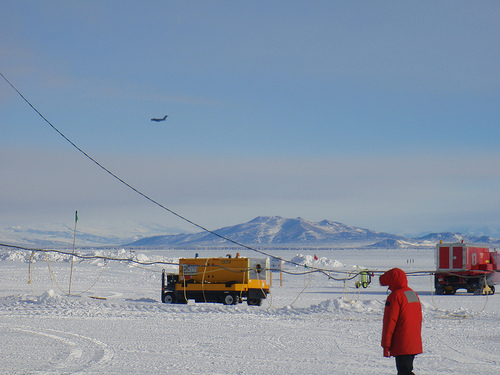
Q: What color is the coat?
A: Red.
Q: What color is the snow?
A: White.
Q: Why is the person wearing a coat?
A: It's cold.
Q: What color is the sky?
A: Blue.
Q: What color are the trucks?
A: Yellow and red.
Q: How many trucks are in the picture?
A: Two.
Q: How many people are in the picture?
A: One.